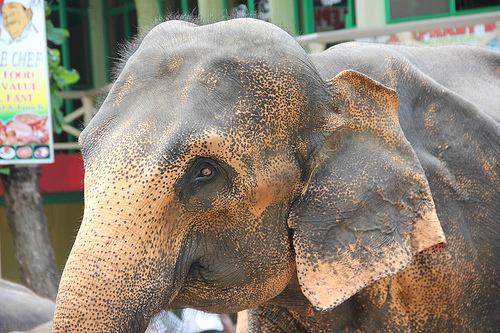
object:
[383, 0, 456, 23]
window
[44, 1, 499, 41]
trim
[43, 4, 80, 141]
green leaves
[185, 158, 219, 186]
eye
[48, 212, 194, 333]
nose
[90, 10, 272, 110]
hair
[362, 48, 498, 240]
show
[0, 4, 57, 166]
sign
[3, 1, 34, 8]
hat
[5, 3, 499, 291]
building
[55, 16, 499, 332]
elephant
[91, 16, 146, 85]
window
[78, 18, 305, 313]
head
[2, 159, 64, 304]
tree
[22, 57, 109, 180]
railing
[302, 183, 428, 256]
veins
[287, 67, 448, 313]
ear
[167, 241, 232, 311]
mouth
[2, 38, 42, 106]
words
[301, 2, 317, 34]
frame